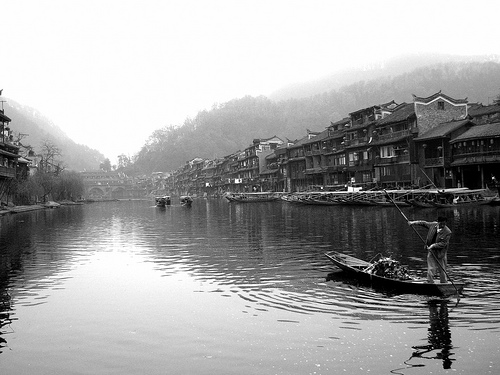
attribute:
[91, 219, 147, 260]
light — reflected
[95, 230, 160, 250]
water — large, still, calm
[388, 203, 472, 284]
man — traveling, rowing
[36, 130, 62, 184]
tree — leafless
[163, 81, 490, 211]
buildings — attached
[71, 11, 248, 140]
sky — hazy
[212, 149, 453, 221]
group — boats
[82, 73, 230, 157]
ski — cloudy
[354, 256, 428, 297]
color — black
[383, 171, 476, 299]
he — long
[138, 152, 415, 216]
boats — parked